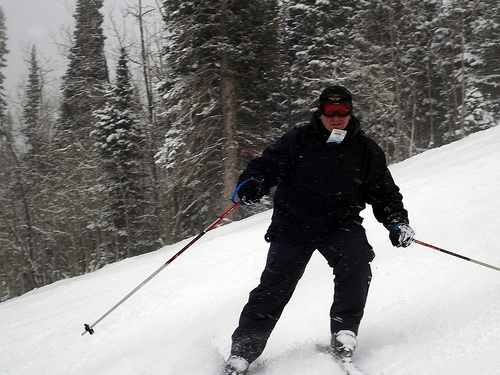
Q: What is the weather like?
A: It is cloudy.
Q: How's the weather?
A: It is cloudy.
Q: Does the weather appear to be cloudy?
A: Yes, it is cloudy.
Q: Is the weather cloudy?
A: Yes, it is cloudy.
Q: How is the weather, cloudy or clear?
A: It is cloudy.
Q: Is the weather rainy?
A: No, it is cloudy.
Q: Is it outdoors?
A: Yes, it is outdoors.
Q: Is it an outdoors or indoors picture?
A: It is outdoors.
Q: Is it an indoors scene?
A: No, it is outdoors.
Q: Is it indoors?
A: No, it is outdoors.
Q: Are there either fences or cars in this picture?
A: No, there are no fences or cars.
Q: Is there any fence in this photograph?
A: No, there are no fences.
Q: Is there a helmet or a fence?
A: No, there are no fences or helmets.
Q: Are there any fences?
A: No, there are no fences.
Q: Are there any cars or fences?
A: No, there are no fences or cars.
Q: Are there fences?
A: No, there are no fences.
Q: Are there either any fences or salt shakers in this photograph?
A: No, there are no fences or salt shakers.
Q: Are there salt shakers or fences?
A: No, there are no fences or salt shakers.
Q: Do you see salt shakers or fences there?
A: No, there are no fences or salt shakers.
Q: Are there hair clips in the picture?
A: No, there are no hair clips.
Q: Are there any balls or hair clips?
A: No, there are no hair clips or balls.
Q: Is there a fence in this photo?
A: No, there are no fences.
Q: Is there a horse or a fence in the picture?
A: No, there are no fences or horses.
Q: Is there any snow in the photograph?
A: Yes, there is snow.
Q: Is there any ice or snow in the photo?
A: Yes, there is snow.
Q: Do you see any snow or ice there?
A: Yes, there is snow.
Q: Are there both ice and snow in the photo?
A: No, there is snow but no ice.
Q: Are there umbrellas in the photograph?
A: No, there are no umbrellas.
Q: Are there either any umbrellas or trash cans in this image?
A: No, there are no umbrellas or trash cans.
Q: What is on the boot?
A: The snow is on the boot.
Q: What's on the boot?
A: The snow is on the boot.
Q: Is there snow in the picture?
A: Yes, there is snow.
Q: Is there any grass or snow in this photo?
A: Yes, there is snow.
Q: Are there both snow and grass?
A: No, there is snow but no grass.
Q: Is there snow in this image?
A: Yes, there is snow.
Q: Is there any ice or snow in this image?
A: Yes, there is snow.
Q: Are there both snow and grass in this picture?
A: No, there is snow but no grass.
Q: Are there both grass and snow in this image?
A: No, there is snow but no grass.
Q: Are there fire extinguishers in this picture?
A: No, there are no fire extinguishers.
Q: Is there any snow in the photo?
A: Yes, there is snow.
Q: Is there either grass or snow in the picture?
A: Yes, there is snow.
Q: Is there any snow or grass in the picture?
A: Yes, there is snow.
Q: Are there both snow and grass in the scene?
A: No, there is snow but no grass.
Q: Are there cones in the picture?
A: No, there are no cones.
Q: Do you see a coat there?
A: Yes, there is a coat.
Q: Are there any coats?
A: Yes, there is a coat.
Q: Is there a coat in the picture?
A: Yes, there is a coat.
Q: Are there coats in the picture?
A: Yes, there is a coat.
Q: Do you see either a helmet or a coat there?
A: Yes, there is a coat.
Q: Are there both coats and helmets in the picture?
A: No, there is a coat but no helmets.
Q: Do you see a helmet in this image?
A: No, there are no helmets.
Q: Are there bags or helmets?
A: No, there are no helmets or bags.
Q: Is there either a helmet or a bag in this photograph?
A: No, there are no helmets or bags.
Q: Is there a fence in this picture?
A: No, there are no fences.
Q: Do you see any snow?
A: Yes, there is snow.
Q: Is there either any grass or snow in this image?
A: Yes, there is snow.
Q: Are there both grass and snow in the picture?
A: No, there is snow but no grass.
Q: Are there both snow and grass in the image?
A: No, there is snow but no grass.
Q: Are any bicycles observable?
A: No, there are no bicycles.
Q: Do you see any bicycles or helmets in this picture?
A: No, there are no bicycles or helmets.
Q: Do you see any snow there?
A: Yes, there is snow.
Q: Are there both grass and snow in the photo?
A: No, there is snow but no grass.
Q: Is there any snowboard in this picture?
A: No, there are no snowboards.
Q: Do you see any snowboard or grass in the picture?
A: No, there are no snowboards or grass.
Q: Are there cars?
A: No, there are no cars.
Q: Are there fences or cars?
A: No, there are no cars or fences.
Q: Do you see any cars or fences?
A: No, there are no cars or fences.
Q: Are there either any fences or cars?
A: No, there are no cars or fences.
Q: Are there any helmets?
A: No, there are no helmets.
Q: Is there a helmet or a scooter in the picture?
A: No, there are no helmets or scooters.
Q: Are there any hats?
A: Yes, there is a hat.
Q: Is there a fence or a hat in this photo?
A: Yes, there is a hat.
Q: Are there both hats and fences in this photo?
A: No, there is a hat but no fences.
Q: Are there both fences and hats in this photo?
A: No, there is a hat but no fences.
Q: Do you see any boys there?
A: No, there are no boys.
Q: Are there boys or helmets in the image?
A: No, there are no boys or helmets.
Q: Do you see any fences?
A: No, there are no fences.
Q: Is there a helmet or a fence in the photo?
A: No, there are no fences or helmets.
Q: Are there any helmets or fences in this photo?
A: No, there are no fences or helmets.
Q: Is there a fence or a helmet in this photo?
A: No, there are no fences or helmets.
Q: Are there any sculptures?
A: No, there are no sculptures.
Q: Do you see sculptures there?
A: No, there are no sculptures.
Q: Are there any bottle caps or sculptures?
A: No, there are no sculptures or bottle caps.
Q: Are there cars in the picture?
A: No, there are no cars.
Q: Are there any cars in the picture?
A: No, there are no cars.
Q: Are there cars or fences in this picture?
A: No, there are no cars or fences.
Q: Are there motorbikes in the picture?
A: No, there are no motorbikes.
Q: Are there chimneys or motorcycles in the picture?
A: No, there are no motorcycles or chimneys.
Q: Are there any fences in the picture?
A: No, there are no fences.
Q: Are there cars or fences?
A: No, there are no fences or cars.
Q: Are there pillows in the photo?
A: No, there are no pillows.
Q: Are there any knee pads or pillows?
A: No, there are no pillows or knee pads.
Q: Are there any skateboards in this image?
A: No, there are no skateboards.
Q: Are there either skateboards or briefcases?
A: No, there are no skateboards or briefcases.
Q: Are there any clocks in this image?
A: No, there are no clocks.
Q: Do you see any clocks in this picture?
A: No, there are no clocks.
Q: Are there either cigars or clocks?
A: No, there are no clocks or cigars.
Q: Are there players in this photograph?
A: No, there are no players.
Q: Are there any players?
A: No, there are no players.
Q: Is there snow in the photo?
A: Yes, there is snow.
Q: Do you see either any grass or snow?
A: Yes, there is snow.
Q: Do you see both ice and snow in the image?
A: No, there is snow but no ice.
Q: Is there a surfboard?
A: No, there are no surfboards.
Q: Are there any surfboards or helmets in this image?
A: No, there are no surfboards or helmets.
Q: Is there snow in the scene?
A: Yes, there is snow.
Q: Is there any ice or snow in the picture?
A: Yes, there is snow.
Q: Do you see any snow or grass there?
A: Yes, there is snow.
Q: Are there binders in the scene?
A: No, there are no binders.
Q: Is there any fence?
A: No, there are no fences.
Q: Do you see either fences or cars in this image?
A: No, there are no fences or cars.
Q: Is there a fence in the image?
A: No, there are no fences.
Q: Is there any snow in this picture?
A: Yes, there is snow.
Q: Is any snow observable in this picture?
A: Yes, there is snow.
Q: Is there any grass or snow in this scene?
A: Yes, there is snow.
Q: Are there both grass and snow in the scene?
A: No, there is snow but no grass.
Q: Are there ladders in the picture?
A: No, there are no ladders.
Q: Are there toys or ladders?
A: No, there are no ladders or toys.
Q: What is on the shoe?
A: The snow is on the shoe.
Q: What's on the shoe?
A: The snow is on the shoe.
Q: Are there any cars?
A: No, there are no cars.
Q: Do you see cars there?
A: No, there are no cars.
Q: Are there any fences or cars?
A: No, there are no cars or fences.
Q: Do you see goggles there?
A: Yes, there are goggles.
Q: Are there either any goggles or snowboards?
A: Yes, there are goggles.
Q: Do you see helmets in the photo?
A: No, there are no helmets.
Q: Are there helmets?
A: No, there are no helmets.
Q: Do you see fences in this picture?
A: No, there are no fences.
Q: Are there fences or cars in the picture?
A: No, there are no fences or cars.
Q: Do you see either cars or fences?
A: No, there are no cars or fences.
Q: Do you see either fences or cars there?
A: No, there are no cars or fences.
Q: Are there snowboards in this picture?
A: No, there are no snowboards.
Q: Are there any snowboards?
A: No, there are no snowboards.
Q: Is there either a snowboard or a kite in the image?
A: No, there are no snowboards or kites.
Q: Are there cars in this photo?
A: No, there are no cars.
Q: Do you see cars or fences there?
A: No, there are no cars or fences.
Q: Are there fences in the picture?
A: No, there are no fences.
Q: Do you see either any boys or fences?
A: No, there are no fences or boys.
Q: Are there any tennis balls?
A: No, there are no tennis balls.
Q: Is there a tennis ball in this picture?
A: No, there are no tennis balls.